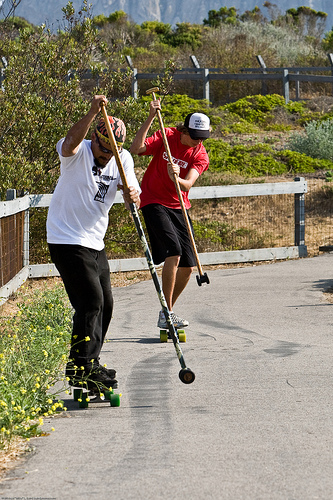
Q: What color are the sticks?
A: Brown.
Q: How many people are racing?
A: Two.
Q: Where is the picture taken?
A: On a roadway.